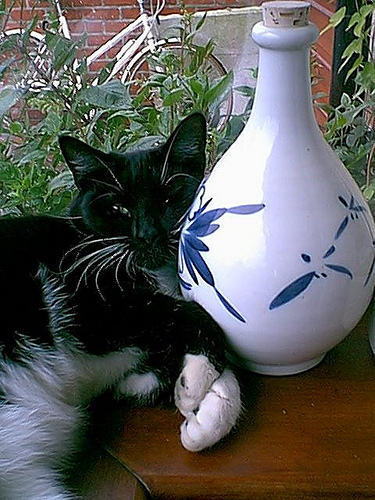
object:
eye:
[111, 200, 135, 220]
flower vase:
[175, 0, 375, 379]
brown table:
[63, 321, 375, 498]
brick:
[84, 20, 105, 35]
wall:
[0, 0, 266, 162]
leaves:
[204, 66, 235, 103]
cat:
[0, 109, 242, 499]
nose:
[138, 224, 160, 246]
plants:
[1, 0, 259, 221]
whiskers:
[114, 249, 129, 295]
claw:
[173, 352, 223, 417]